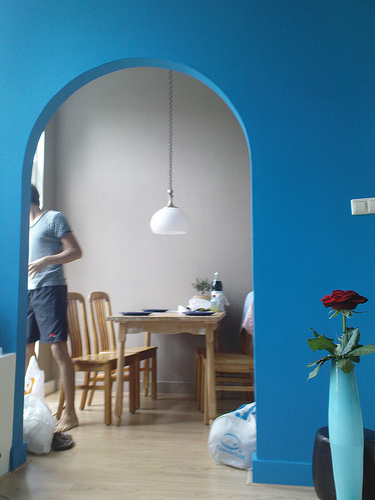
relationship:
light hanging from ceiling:
[152, 190, 192, 239] [119, 63, 209, 72]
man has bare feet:
[26, 162, 99, 432] [45, 414, 79, 433]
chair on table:
[56, 291, 136, 426] [107, 306, 230, 425]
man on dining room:
[26, 184, 83, 434] [21, 62, 262, 496]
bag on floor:
[23, 354, 57, 454] [0, 388, 319, 498]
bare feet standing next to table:
[54, 413, 79, 433] [108, 301, 228, 420]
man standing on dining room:
[26, 184, 83, 434] [21, 62, 262, 496]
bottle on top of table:
[208, 268, 226, 311] [107, 306, 230, 425]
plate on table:
[114, 307, 155, 319] [103, 298, 221, 428]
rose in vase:
[312, 292, 357, 381] [326, 361, 363, 497]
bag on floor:
[21, 363, 49, 439] [45, 393, 210, 469]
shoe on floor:
[49, 428, 79, 449] [45, 393, 210, 469]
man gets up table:
[26, 184, 83, 434] [103, 296, 226, 416]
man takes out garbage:
[26, 184, 83, 434] [26, 376, 62, 453]